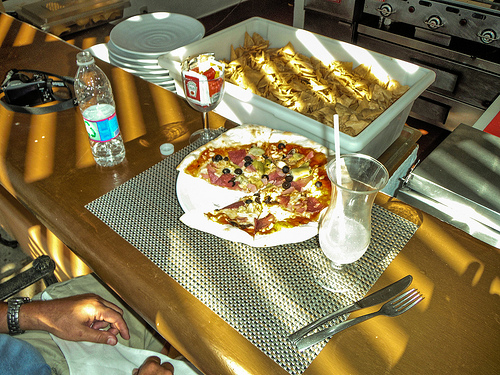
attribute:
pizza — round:
[175, 126, 346, 259]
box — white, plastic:
[164, 16, 430, 153]